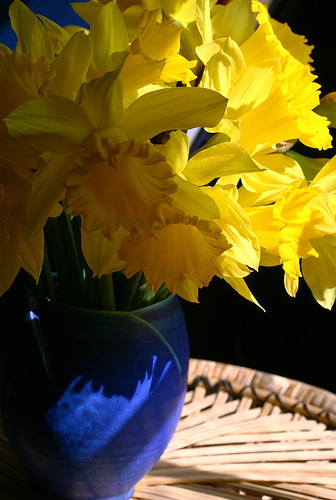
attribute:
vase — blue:
[0, 276, 188, 498]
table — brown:
[128, 357, 335, 499]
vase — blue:
[36, 241, 233, 491]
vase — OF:
[17, 293, 192, 485]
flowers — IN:
[4, 41, 325, 295]